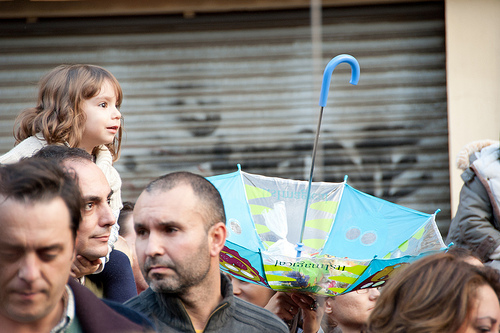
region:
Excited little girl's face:
[17, 65, 127, 147]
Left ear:
[201, 220, 234, 255]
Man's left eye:
[161, 225, 186, 236]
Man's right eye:
[129, 227, 149, 237]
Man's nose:
[141, 240, 167, 260]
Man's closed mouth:
[141, 261, 181, 277]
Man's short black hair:
[135, 165, 226, 215]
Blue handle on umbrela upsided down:
[315, 50, 366, 111]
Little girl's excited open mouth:
[101, 121, 116, 127]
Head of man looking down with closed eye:
[0, 156, 83, 318]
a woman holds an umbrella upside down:
[181, 49, 456, 329]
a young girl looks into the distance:
[6, 51, 127, 246]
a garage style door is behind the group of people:
[3, 26, 446, 228]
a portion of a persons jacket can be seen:
[443, 133, 495, 262]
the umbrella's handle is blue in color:
[312, 38, 362, 104]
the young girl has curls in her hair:
[17, 70, 127, 141]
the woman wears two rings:
[278, 289, 320, 319]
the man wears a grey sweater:
[131, 286, 291, 330]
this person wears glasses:
[352, 284, 394, 296]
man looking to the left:
[30, 146, 116, 279]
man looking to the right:
[110, 169, 286, 331]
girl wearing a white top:
[0, 64, 125, 275]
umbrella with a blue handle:
[184, 47, 454, 332]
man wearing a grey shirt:
[105, 169, 296, 331]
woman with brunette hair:
[362, 251, 497, 331]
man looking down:
[1, 156, 151, 331]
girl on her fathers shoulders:
[0, 59, 135, 308]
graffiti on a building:
[134, 122, 449, 209]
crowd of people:
[0, 62, 498, 331]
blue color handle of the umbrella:
[321, 48, 358, 119]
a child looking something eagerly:
[27, 50, 141, 156]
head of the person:
[116, 167, 225, 296]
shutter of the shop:
[188, 12, 456, 193]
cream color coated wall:
[452, 15, 497, 141]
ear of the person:
[206, 215, 224, 260]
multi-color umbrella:
[225, 202, 369, 284]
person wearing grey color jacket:
[455, 151, 490, 257]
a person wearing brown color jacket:
[68, 275, 124, 330]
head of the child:
[26, 54, 127, 139]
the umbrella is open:
[193, 40, 450, 285]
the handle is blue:
[272, 37, 377, 127]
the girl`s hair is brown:
[6, 49, 137, 154]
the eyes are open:
[87, 90, 121, 111]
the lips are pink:
[96, 120, 129, 142]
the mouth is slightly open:
[98, 120, 125, 139]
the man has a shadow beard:
[120, 236, 222, 298]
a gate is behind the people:
[122, 17, 438, 227]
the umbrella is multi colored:
[169, 155, 461, 316]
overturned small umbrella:
[160, 40, 457, 299]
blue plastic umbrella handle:
[310, 35, 360, 110]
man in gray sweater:
[102, 172, 292, 332]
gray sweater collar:
[150, 278, 240, 331]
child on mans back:
[7, 65, 134, 162]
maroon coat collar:
[72, 278, 141, 331]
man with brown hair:
[2, 165, 79, 330]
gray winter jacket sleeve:
[445, 145, 499, 272]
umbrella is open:
[194, 52, 451, 299]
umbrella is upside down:
[198, 56, 451, 295]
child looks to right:
[1, 61, 126, 252]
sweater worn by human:
[123, 272, 293, 332]